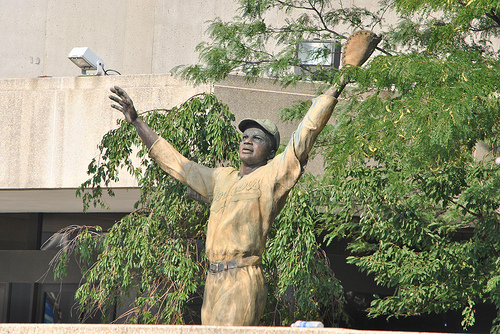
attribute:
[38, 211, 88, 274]
needles — green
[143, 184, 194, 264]
needles — green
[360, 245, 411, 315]
needles — green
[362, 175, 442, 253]
needles — green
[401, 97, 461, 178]
needles — green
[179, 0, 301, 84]
needles — green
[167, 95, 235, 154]
needles — green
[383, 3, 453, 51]
needles — green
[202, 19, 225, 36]
needles — green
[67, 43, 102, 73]
light — square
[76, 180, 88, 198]
leaves — green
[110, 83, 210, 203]
arm — extended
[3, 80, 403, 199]
surface — cement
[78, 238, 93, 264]
leaves — small, green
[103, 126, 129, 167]
leaves — green, small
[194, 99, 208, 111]
leaves — small, green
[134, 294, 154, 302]
leaves — green, small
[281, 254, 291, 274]
leaves — small, green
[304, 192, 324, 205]
leaves — green, small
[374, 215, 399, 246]
leaves — small, green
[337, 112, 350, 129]
leaves — green, small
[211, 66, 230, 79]
leaves — small, green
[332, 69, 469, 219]
leaves — small, green